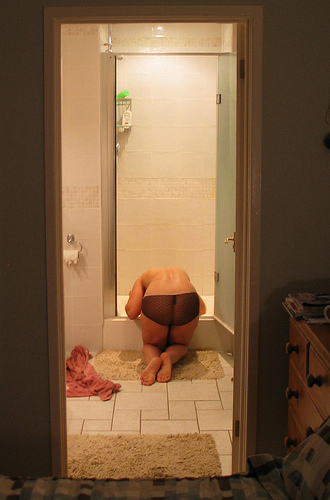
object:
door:
[45, 4, 267, 471]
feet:
[157, 351, 172, 382]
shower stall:
[100, 49, 219, 322]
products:
[117, 89, 129, 98]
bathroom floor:
[63, 391, 88, 441]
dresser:
[285, 293, 330, 453]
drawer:
[287, 369, 323, 441]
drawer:
[290, 320, 312, 384]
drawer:
[308, 343, 330, 419]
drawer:
[284, 421, 303, 460]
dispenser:
[67, 232, 75, 245]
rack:
[116, 98, 133, 133]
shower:
[114, 53, 125, 65]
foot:
[140, 354, 162, 387]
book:
[281, 291, 328, 320]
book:
[303, 316, 327, 325]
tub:
[117, 291, 213, 318]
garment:
[66, 345, 121, 402]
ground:
[63, 351, 232, 475]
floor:
[213, 434, 234, 477]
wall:
[59, 23, 104, 353]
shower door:
[213, 51, 236, 336]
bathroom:
[60, 22, 238, 478]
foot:
[156, 351, 171, 384]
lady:
[125, 265, 207, 387]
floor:
[180, 421, 219, 430]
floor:
[218, 377, 235, 410]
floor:
[143, 392, 170, 418]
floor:
[122, 392, 143, 424]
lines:
[166, 384, 171, 422]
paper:
[63, 249, 79, 266]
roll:
[67, 232, 82, 252]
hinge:
[235, 419, 240, 437]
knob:
[285, 339, 300, 356]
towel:
[65, 345, 122, 401]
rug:
[94, 345, 225, 382]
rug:
[66, 430, 223, 480]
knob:
[307, 374, 325, 389]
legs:
[140, 314, 169, 349]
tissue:
[63, 249, 80, 266]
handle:
[224, 231, 237, 252]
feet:
[140, 356, 162, 386]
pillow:
[284, 421, 330, 498]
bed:
[1, 414, 330, 497]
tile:
[168, 397, 200, 420]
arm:
[127, 279, 144, 319]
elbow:
[125, 298, 141, 317]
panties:
[141, 292, 200, 327]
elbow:
[199, 295, 208, 313]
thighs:
[169, 315, 199, 345]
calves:
[142, 344, 159, 358]